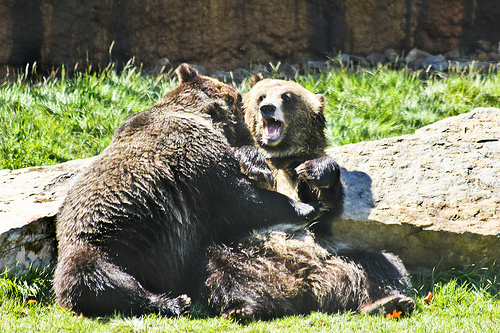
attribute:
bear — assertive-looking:
[55, 58, 332, 320]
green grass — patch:
[364, 69, 474, 134]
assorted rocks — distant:
[368, 45, 421, 68]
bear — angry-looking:
[199, 77, 415, 312]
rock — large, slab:
[265, 80, 485, 296]